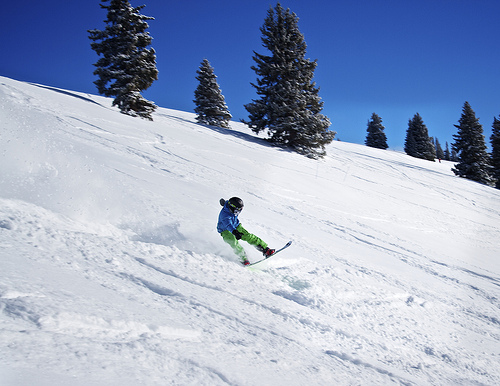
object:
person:
[214, 197, 278, 266]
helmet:
[228, 197, 246, 212]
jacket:
[217, 206, 240, 232]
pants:
[222, 224, 270, 261]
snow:
[0, 75, 499, 386]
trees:
[89, 0, 161, 120]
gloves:
[231, 228, 245, 240]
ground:
[0, 74, 499, 384]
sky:
[0, 0, 498, 159]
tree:
[241, 2, 339, 163]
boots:
[262, 247, 276, 256]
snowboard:
[240, 238, 295, 270]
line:
[322, 346, 412, 385]